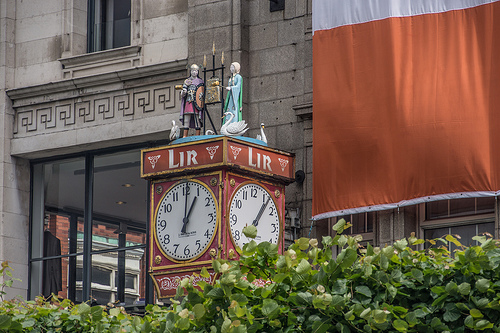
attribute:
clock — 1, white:
[144, 179, 217, 261]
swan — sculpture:
[221, 111, 255, 137]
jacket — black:
[332, 82, 381, 106]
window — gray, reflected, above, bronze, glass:
[103, 259, 129, 299]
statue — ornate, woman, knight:
[184, 71, 208, 121]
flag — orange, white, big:
[334, 3, 394, 32]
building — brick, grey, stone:
[247, 24, 273, 49]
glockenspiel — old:
[168, 68, 264, 134]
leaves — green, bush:
[281, 268, 321, 295]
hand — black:
[179, 208, 201, 230]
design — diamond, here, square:
[136, 95, 158, 121]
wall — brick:
[9, 3, 73, 62]